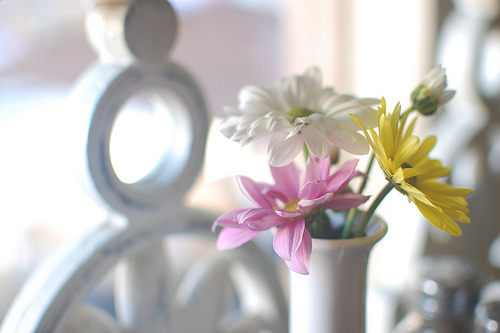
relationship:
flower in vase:
[352, 98, 472, 239] [270, 207, 390, 332]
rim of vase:
[271, 204, 388, 252] [270, 207, 390, 332]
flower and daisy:
[352, 98, 472, 239] [208, 153, 372, 275]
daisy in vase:
[208, 153, 372, 275] [270, 207, 390, 332]